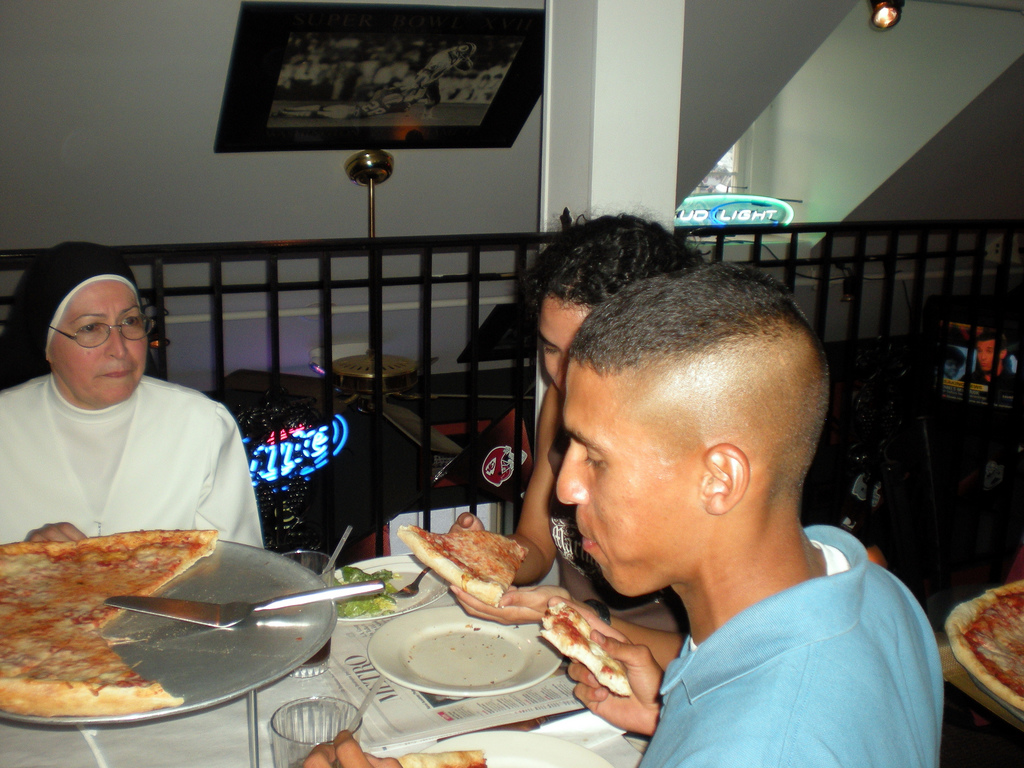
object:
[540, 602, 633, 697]
pizza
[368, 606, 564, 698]
plates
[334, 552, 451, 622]
plates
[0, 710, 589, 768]
table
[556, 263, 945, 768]
man